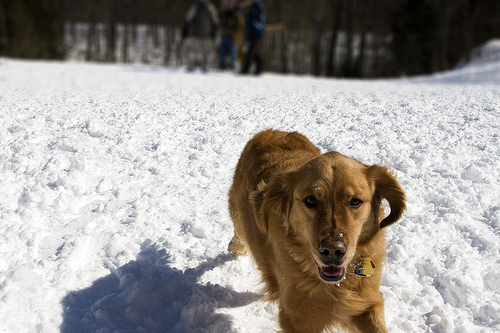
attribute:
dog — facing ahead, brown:
[227, 126, 407, 331]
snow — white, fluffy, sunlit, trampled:
[3, 57, 500, 332]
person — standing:
[180, 0, 223, 71]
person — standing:
[212, 2, 243, 73]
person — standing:
[239, 1, 269, 77]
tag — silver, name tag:
[355, 254, 379, 278]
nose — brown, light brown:
[315, 228, 349, 259]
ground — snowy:
[0, 50, 499, 332]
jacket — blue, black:
[242, 2, 268, 44]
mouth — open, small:
[312, 252, 353, 287]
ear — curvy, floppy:
[246, 167, 295, 236]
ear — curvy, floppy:
[367, 160, 408, 228]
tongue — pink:
[319, 266, 344, 280]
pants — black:
[240, 38, 265, 75]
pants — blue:
[215, 33, 238, 71]